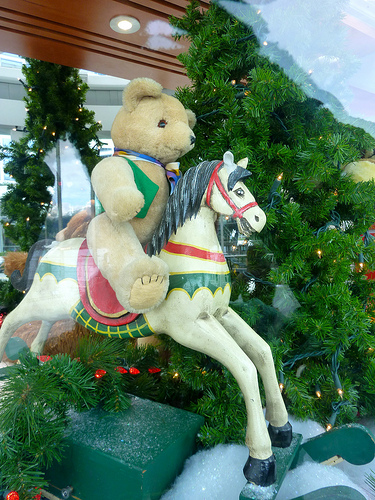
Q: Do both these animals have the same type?
A: No, they are horses and bears.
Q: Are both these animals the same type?
A: No, they are horses and bears.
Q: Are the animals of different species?
A: Yes, they are horses and bears.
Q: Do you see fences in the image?
A: No, there are no fences.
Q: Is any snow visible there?
A: Yes, there is snow.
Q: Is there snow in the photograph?
A: Yes, there is snow.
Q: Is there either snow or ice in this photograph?
A: Yes, there is snow.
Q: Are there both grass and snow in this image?
A: No, there is snow but no grass.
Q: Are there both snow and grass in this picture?
A: No, there is snow but no grass.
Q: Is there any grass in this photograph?
A: No, there is no grass.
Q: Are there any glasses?
A: No, there are no glasses.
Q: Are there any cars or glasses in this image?
A: No, there are no glasses or cars.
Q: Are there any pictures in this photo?
A: No, there are no pictures.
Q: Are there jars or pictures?
A: No, there are no pictures or jars.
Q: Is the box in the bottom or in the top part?
A: The box is in the bottom of the image.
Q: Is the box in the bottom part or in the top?
A: The box is in the bottom of the image.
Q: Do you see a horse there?
A: Yes, there is a horse.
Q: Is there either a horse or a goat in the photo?
A: Yes, there is a horse.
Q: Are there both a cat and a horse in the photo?
A: No, there is a horse but no cats.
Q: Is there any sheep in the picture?
A: No, there is no sheep.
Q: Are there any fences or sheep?
A: No, there are no sheep or fences.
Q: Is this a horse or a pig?
A: This is a horse.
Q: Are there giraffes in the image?
A: No, there are no giraffes.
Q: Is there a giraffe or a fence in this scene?
A: No, there are no giraffes or fences.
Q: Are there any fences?
A: No, there are no fences.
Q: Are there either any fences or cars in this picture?
A: No, there are no fences or cars.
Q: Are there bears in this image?
A: Yes, there is a bear.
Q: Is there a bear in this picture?
A: Yes, there is a bear.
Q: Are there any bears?
A: Yes, there is a bear.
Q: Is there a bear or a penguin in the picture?
A: Yes, there is a bear.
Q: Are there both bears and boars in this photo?
A: No, there is a bear but no boars.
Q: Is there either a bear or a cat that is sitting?
A: Yes, the bear is sitting.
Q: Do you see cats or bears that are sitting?
A: Yes, the bear is sitting.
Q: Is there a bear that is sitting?
A: Yes, there is a bear that is sitting.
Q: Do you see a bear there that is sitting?
A: Yes, there is a bear that is sitting.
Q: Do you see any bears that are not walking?
A: Yes, there is a bear that is sitting .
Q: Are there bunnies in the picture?
A: No, there are no bunnies.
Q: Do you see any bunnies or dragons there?
A: No, there are no bunnies or dragons.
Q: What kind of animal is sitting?
A: The animal is a bear.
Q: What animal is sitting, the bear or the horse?
A: The bear is sitting.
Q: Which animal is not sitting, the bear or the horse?
A: The horse is not sitting.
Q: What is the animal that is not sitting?
A: The animal is a horse.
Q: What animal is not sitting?
A: The animal is a horse.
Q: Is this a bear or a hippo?
A: This is a bear.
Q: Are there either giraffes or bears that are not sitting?
A: No, there is a bear but it is sitting.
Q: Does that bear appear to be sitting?
A: Yes, the bear is sitting.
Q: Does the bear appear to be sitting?
A: Yes, the bear is sitting.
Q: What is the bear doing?
A: The bear is sitting.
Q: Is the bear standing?
A: No, the bear is sitting.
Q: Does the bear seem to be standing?
A: No, the bear is sitting.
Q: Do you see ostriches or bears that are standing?
A: No, there is a bear but it is sitting.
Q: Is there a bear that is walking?
A: No, there is a bear but it is sitting.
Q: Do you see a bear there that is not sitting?
A: No, there is a bear but it is sitting.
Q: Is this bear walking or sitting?
A: The bear is sitting.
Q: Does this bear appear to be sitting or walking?
A: The bear is sitting.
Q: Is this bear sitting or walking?
A: The bear is sitting.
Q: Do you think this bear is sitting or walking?
A: The bear is sitting.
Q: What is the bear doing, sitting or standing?
A: The bear is sitting.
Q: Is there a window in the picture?
A: Yes, there is a window.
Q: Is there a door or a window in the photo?
A: Yes, there is a window.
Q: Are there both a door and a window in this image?
A: No, there is a window but no doors.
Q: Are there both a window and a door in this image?
A: No, there is a window but no doors.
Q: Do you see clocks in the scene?
A: No, there are no clocks.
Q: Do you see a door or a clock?
A: No, there are no clocks or doors.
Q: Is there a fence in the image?
A: No, there are no fences.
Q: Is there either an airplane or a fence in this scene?
A: No, there are no fences or airplanes.